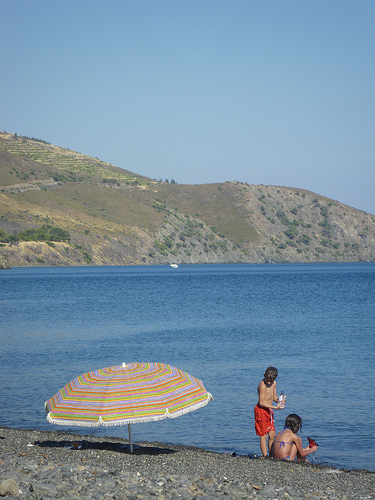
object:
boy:
[254, 365, 287, 458]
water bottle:
[274, 390, 285, 409]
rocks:
[46, 472, 143, 493]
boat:
[169, 263, 178, 269]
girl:
[273, 413, 318, 462]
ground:
[0, 447, 373, 495]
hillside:
[0, 131, 373, 266]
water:
[1, 259, 374, 472]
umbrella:
[44, 361, 214, 453]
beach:
[0, 428, 373, 498]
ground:
[43, 158, 262, 234]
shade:
[31, 435, 179, 456]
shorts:
[254, 404, 276, 436]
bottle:
[277, 390, 285, 408]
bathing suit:
[274, 428, 295, 460]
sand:
[6, 428, 330, 496]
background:
[0, 130, 374, 268]